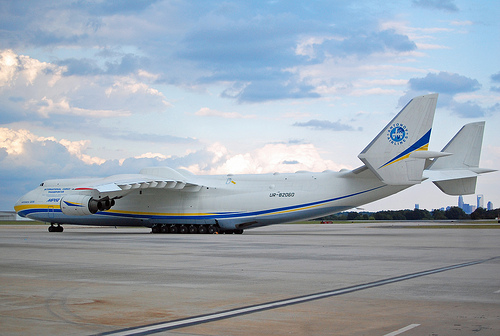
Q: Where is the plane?
A: On the runway.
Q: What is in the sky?
A: Clouds.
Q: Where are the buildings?
A: In the distance.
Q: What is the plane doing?
A: Sitting on the runway.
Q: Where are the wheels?
A: Under the plane.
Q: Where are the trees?
A: In front of the buildings.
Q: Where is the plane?
A: On the runway.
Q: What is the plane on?
A: The tarmac.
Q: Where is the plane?
A: Airport.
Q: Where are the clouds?
A: In the sky.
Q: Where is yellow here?
A: On the plane?.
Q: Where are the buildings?
A: By the trees.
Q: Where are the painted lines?
A: On the ground.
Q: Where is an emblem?
A: On the tail.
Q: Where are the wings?
A: Side of plane.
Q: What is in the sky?
A: Clouds.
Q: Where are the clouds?
A: In the sky.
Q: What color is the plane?
A: White.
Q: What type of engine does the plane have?
A: Turbine.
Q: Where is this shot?
A: Air field.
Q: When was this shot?
A: Daytime.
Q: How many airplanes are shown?
A: 1.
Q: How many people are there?
A: 0.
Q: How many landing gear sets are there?
A: 3.